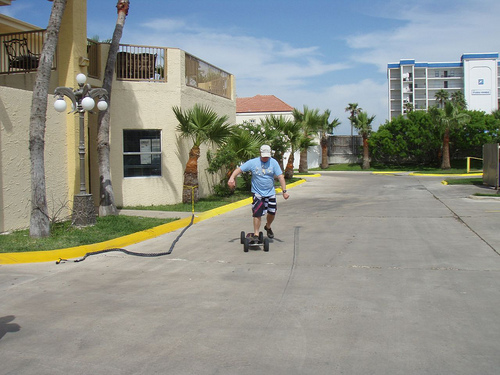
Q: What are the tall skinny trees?
A: Palm trees.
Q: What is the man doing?
A: Skateboarding.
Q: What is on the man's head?
A: Hat.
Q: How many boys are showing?
A: One.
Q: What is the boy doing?
A: Riding a skateboard.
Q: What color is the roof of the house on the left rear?
A: Red.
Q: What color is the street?
A: Gray.